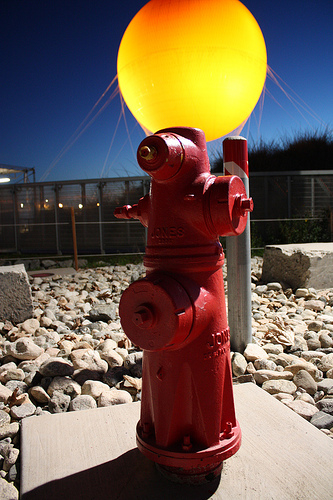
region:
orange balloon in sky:
[106, 17, 277, 155]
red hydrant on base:
[108, 124, 245, 468]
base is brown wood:
[71, 364, 309, 498]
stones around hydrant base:
[8, 315, 127, 392]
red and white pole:
[192, 78, 270, 351]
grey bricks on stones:
[3, 248, 42, 328]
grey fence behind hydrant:
[16, 179, 308, 237]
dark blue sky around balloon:
[3, 18, 103, 173]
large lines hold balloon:
[45, 78, 179, 198]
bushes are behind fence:
[188, 123, 329, 166]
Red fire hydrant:
[110, 123, 246, 470]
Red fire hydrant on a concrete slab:
[15, 118, 326, 493]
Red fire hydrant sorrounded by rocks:
[16, 121, 319, 498]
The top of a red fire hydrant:
[129, 120, 223, 174]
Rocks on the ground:
[15, 333, 99, 381]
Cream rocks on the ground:
[6, 330, 112, 395]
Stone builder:
[3, 254, 40, 322]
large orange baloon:
[98, 1, 284, 142]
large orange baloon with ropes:
[95, 7, 290, 140]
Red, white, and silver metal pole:
[217, 136, 256, 355]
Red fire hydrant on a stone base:
[112, 125, 264, 473]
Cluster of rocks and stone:
[1, 328, 142, 411]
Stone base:
[26, 377, 329, 497]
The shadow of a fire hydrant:
[21, 443, 222, 497]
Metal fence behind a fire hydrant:
[1, 174, 331, 256]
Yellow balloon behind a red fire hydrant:
[113, 1, 269, 144]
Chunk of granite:
[260, 237, 328, 287]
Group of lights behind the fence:
[11, 195, 111, 210]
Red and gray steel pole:
[216, 133, 255, 348]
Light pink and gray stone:
[240, 341, 266, 358]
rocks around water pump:
[3, 249, 330, 496]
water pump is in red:
[112, 124, 253, 481]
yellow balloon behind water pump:
[109, 1, 282, 141]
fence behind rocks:
[0, 150, 331, 265]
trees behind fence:
[1, 127, 329, 258]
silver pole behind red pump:
[215, 134, 258, 358]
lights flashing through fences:
[0, 169, 320, 255]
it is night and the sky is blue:
[2, 0, 327, 177]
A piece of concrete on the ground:
[25, 412, 127, 496]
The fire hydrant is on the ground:
[108, 119, 289, 494]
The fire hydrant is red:
[170, 280, 219, 411]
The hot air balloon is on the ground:
[115, 0, 272, 147]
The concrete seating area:
[260, 237, 330, 295]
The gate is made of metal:
[9, 171, 127, 249]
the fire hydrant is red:
[113, 125, 252, 485]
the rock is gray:
[88, 303, 116, 319]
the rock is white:
[243, 342, 269, 359]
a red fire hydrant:
[99, 108, 254, 499]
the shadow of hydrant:
[0, 424, 245, 497]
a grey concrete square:
[18, 378, 331, 498]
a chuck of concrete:
[0, 253, 38, 332]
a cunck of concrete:
[255, 232, 331, 294]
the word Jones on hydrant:
[145, 219, 190, 248]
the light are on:
[0, 195, 107, 215]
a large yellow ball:
[100, 2, 276, 141]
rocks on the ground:
[42, 275, 115, 390]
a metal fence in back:
[1, 148, 324, 268]